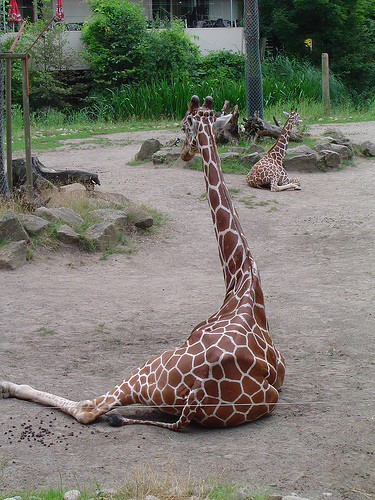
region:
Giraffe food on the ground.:
[16, 411, 79, 457]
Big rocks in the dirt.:
[52, 481, 135, 496]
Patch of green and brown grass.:
[177, 471, 209, 494]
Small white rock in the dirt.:
[320, 487, 334, 497]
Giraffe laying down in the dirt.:
[249, 111, 311, 191]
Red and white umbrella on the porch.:
[8, 2, 24, 23]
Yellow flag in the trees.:
[300, 35, 320, 54]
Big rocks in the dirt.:
[29, 179, 155, 249]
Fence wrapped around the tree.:
[239, 11, 267, 120]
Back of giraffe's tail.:
[105, 402, 204, 432]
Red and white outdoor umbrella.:
[5, 2, 23, 22]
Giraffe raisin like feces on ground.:
[10, 415, 72, 450]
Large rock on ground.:
[84, 205, 130, 251]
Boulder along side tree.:
[320, 149, 339, 169]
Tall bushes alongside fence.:
[78, 7, 154, 93]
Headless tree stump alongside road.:
[321, 51, 330, 111]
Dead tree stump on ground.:
[246, 115, 300, 140]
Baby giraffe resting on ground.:
[249, 107, 308, 194]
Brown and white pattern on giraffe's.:
[187, 347, 259, 402]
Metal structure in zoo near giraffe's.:
[1, 50, 41, 210]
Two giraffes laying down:
[2, 95, 306, 429]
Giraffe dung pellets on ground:
[2, 408, 131, 452]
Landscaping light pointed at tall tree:
[167, 136, 184, 146]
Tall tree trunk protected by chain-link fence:
[240, 1, 266, 127]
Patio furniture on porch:
[186, 16, 240, 27]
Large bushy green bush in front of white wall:
[80, 1, 199, 73]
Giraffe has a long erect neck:
[178, 92, 273, 328]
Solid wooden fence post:
[319, 50, 332, 112]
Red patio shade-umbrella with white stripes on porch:
[2, 0, 25, 32]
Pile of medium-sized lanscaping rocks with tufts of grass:
[1, 186, 157, 273]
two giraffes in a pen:
[17, 103, 327, 454]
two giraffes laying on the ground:
[29, 107, 306, 421]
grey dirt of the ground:
[319, 383, 370, 477]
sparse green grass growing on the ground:
[43, 135, 134, 154]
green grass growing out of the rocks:
[19, 182, 148, 248]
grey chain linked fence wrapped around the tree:
[230, 0, 270, 129]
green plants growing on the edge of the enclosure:
[82, 47, 267, 114]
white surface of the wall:
[201, 36, 236, 49]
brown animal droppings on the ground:
[4, 402, 97, 453]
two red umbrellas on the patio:
[0, 0, 68, 31]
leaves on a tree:
[97, 14, 178, 79]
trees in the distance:
[304, 5, 368, 37]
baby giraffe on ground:
[235, 90, 317, 211]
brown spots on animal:
[195, 310, 255, 385]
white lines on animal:
[203, 309, 259, 369]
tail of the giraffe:
[83, 377, 214, 464]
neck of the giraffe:
[195, 136, 247, 256]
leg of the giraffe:
[0, 357, 105, 432]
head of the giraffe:
[158, 86, 229, 161]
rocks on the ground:
[51, 198, 138, 255]